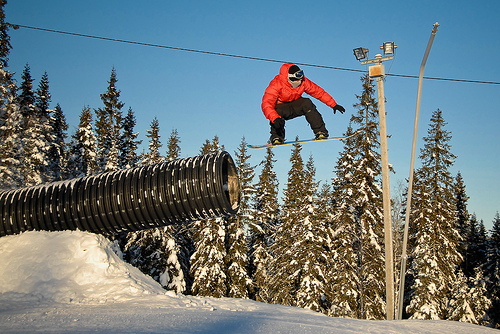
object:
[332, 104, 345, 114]
glove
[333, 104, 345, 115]
hand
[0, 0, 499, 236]
blue sky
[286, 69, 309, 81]
goggles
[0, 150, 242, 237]
tube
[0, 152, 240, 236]
snow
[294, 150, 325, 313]
tree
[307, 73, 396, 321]
tree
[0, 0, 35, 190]
tree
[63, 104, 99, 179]
tree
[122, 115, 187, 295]
tree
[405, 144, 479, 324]
snow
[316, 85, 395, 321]
snow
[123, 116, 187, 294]
snow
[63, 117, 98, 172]
snow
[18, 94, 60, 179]
snow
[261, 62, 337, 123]
jacket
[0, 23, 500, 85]
black wire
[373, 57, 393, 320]
light pole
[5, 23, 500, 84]
electricity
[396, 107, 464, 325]
tree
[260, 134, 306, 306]
tree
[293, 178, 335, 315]
tree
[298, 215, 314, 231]
snow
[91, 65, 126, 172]
tree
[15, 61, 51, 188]
tree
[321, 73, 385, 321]
tree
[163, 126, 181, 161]
tree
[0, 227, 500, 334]
snow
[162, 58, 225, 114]
blue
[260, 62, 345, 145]
man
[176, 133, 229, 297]
tree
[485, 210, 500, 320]
trees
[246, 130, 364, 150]
board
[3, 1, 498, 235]
clouds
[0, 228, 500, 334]
ground